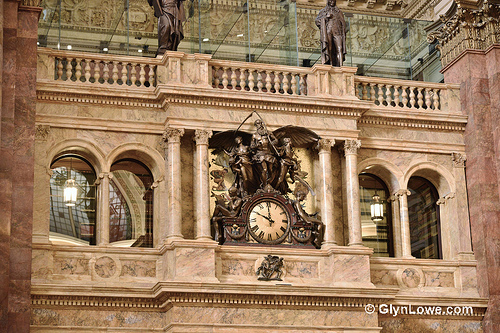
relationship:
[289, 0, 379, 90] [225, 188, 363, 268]
statue over clock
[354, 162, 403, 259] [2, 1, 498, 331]
window of building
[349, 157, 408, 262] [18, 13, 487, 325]
window of building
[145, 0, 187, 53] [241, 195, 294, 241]
statue over clock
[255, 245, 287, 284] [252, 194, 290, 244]
emblem over clock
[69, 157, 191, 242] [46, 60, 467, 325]
window of a building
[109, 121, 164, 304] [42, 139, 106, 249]
ancient window arch way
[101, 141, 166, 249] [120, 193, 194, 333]
ancient window arch way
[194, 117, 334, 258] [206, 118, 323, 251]
clock a center clock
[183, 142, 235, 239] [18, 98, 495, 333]
wall on side of a building